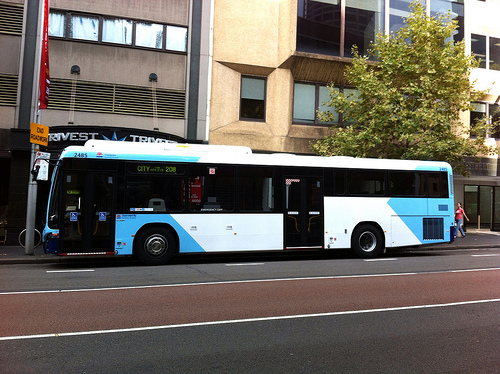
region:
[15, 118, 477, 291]
This is a bus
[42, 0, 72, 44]
Pane of a window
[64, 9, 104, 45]
Pane of a window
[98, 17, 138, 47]
Pane of a window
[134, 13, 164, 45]
Pane of a window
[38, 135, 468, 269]
Bus on the street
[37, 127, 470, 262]
Bus is on the street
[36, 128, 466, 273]
Blue and white bus on the street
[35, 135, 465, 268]
Blue and white bus is on the street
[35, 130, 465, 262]
Bus is parked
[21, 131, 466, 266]
Blue and white bus is parked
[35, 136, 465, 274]
Bus parked on the street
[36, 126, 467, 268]
Bus is parked on the street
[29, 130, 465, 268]
Blue and white bus parked on the street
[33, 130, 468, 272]
Blue and white bus is parked on the street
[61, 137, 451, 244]
a blue and white bus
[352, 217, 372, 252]
the tire on the bus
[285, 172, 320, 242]
the door on the bus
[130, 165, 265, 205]
the windows on the bus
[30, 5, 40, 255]
a pole next to the bus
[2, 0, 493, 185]
a building behind the bus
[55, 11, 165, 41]
a window on the building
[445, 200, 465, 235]
a lady walking in front of the building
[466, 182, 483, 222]
the door of the building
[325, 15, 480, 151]
a tree in front of the building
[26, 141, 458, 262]
this is a bus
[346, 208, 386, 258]
this is a wheel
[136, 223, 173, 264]
this is a wheel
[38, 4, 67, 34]
this is a window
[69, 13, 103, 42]
this is a window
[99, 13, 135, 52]
this is a window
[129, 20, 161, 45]
this is a window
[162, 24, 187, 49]
this is a window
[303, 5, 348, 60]
this is a window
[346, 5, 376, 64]
this is a window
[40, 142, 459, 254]
a white and aqua bus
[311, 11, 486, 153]
a tree to the right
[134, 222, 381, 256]
two tires of the bus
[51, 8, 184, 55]
some crystal windows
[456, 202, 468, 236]
a person behind the bus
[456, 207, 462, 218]
the t-shirt is red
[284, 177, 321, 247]
the exit door of the bus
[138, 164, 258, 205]
wide passengers window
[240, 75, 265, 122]
a black window above the bus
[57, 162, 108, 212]
the bus driver cabin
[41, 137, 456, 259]
blue and white bus next to curb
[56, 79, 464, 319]
this is a large bus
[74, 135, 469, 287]
the bus is long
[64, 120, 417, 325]
the bus is blue and white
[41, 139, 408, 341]
this is a public transit bus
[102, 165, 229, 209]
the windows are black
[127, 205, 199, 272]
the wheels are black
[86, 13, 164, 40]
these are windows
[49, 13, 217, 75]
the windows are white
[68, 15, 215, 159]
the building is gray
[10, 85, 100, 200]
the sign is yellow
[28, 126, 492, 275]
Bus on the street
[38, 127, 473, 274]
Bus on the road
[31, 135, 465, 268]
Bus near the curb